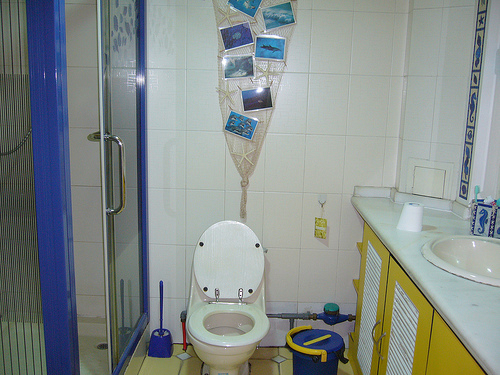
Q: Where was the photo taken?
A: In a bathroom.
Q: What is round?
A: Toilet.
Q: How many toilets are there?
A: One.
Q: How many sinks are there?
A: Only one.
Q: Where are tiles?
A: On the wall.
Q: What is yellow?
A: Cabinets.